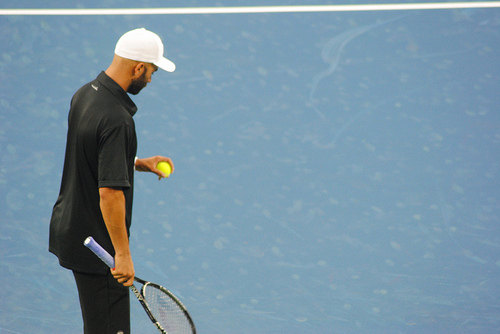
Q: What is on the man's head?
A: A white cap.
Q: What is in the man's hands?
A: A tennis ball and racket.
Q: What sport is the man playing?
A: Tennis.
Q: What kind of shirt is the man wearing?
A: A black polo.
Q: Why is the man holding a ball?
A: Playing a game of tennis.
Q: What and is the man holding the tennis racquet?
A: Right hand.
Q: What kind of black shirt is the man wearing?
A: Short sleeve.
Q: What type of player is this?
A: Tennis player.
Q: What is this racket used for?
A: To hit the ball.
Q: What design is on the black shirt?
A: Yellow stripe on back.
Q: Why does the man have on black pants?
A: Match with shirt.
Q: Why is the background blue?
A: Sky.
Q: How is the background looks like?
A: Blue.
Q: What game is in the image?
A: Tennis.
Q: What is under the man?
A: Blue ground.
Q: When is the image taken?
A: Playing.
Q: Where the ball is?
A: In left hand.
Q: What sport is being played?
A: Tennis.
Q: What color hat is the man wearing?
A: White.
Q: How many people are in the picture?
A: 1.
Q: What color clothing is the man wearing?
A: Black.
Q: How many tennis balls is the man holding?
A: 1.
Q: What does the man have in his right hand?
A: Tennis racket.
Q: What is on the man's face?
A: Beard.